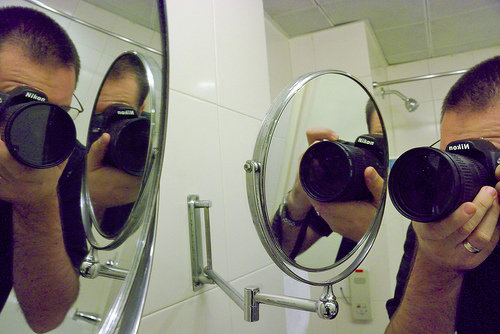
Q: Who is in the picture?
A: A man.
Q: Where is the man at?
A: A bathroom.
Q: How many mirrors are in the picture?
A: Two.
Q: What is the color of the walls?
A: White.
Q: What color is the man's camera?
A: Black.